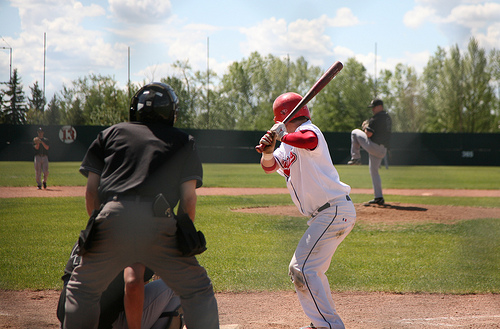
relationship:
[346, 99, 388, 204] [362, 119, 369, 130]
pitcher to ball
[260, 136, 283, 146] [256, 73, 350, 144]
fingers wrapped around bat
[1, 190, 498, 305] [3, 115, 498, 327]
green grass on field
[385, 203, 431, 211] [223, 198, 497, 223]
shadow on mound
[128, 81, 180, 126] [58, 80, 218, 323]
hat on umpire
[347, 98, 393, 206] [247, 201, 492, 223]
pitcher in dirt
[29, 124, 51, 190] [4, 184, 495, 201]
player in dirt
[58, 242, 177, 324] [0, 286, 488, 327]
player in dirt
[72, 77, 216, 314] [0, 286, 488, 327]
player in dirt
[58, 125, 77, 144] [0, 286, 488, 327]
logo in dirt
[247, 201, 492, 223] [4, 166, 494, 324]
dirt of field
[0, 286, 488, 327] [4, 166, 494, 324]
dirt of field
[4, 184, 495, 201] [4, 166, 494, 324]
dirt of field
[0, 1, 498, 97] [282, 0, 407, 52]
cloud in sky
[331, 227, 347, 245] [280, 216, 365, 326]
dirt on pants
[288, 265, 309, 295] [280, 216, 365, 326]
dirt on pants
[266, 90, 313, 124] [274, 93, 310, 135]
helmet on batter's head